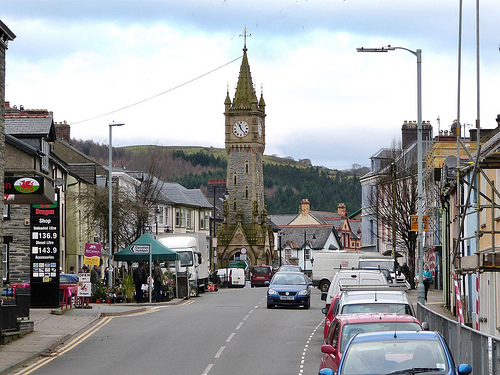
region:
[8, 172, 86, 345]
Gas station on left side.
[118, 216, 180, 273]
Green tent on side of road.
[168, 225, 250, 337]
White truck near tent.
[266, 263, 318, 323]
Blue car driving on road.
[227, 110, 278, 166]
White clock in tower.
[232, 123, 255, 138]
Black hands on clock.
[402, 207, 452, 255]
Yellow sign on silver pole.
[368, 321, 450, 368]
Blue car on side of road.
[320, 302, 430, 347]
Red car on side of road.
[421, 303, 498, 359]
Silver fence near road.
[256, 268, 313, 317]
This is a car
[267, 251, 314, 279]
This is a car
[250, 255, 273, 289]
This is a car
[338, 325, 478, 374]
This is a car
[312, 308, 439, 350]
This is a car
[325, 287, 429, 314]
This is a car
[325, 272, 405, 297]
This is a car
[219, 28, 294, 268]
This is a tower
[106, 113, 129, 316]
This is a pole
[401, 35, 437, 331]
This is a pole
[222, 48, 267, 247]
tan block clock tower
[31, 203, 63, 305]
gas station price sign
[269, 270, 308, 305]
blue car on street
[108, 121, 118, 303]
grey metal street lamp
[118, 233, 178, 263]
green fabric tent top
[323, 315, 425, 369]
red car parked at curb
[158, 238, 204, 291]
delivery truck at curb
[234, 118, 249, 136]
white and black clock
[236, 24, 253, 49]
weather vane on tower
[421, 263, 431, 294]
person wearing blue shirt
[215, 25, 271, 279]
a clock tower in distance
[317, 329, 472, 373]
a parked blue car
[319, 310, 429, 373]
a parked red car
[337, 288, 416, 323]
a parked silver van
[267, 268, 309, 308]
a blue car in street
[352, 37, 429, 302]
an overhead street light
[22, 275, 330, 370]
a paved city street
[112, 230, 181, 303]
a pop up green tent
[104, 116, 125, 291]
an overhead street light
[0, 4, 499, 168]
a cloudy blue sky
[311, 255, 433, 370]
Cars parked on the side of the street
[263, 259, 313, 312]
The car is blue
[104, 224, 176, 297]
The tent is green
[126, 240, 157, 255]
Black and white sign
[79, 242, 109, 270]
Purple and yellow sign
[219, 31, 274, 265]
the clock tower is tall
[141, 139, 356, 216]
Hills with trees behind the buildings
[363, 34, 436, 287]
Tall grey light pole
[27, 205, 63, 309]
The sign is tall and black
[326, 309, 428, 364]
The car is red